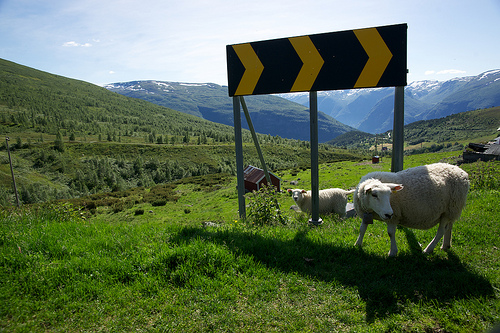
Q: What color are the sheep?
A: Beige.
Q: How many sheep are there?
A: Two.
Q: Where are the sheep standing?
A: By a street sign.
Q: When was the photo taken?
A: Daytime.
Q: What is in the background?
A: Mountains.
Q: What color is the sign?
A: Black and yellow.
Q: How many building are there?
A: Three.